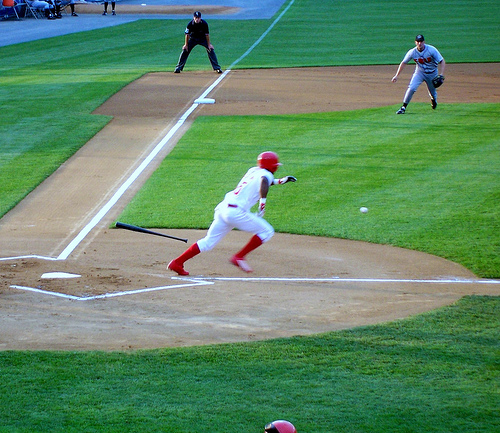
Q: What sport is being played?
A: Baseball.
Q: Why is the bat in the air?
A: Just hit the ball.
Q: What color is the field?
A: Green.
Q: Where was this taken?
A: Baseball field.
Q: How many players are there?
A: 2.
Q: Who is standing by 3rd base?
A: Umpire.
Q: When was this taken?
A: Daytime.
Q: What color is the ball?
A: White.